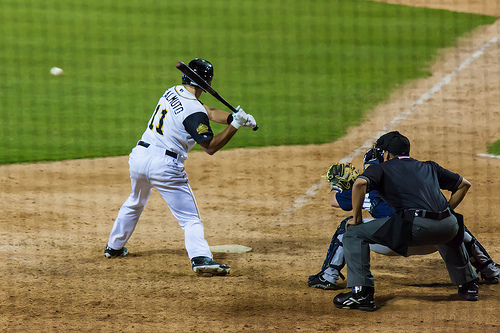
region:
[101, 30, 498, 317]
Men playing baseball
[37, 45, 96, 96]
baseball in the air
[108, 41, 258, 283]
man in hitting stance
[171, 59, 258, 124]
man holding black bat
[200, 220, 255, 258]
hexagon shaped object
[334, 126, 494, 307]
empire watching the pitch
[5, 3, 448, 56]
short green grassy field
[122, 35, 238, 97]
man has black helmet on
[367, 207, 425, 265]
black towel hanging out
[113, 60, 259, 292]
man in white baseball uniform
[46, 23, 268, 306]
a baseball player focused on the ball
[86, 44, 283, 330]
a baseball player at bat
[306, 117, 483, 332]
an umpire and a catcher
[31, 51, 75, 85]
a baseball speeding towards the batter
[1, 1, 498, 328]
a baseball game going on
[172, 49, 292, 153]
a black baseball bat and a batting helmet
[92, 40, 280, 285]
an athlete looking to hit the ball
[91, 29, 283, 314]
an athlete looking to swing his bat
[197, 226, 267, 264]
home plate on a baseball diamond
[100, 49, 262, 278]
A baseball player preparing to swing his bat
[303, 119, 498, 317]
A catcher standing at home plate.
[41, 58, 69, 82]
a baseball flying through the air.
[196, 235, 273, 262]
a base near a baseball player.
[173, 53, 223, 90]
a hard blue hat.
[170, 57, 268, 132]
a bat in a players hand.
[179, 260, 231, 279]
a foot on the right shoe.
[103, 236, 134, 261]
the left shoe on a foot.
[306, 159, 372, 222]
a catchers MIT on a catcher.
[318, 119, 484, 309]
a man dressed in dark blue.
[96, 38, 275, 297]
a baseball player preparing to bat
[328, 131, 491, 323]
umpire getting ready to judge the pitch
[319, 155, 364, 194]
a catcher's mitt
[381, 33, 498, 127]
chalk first base line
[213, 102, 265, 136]
white batting gloves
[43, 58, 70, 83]
a baseball being thrown toward the catcher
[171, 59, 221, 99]
a black batting helmet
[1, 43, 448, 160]
the infield is covered with grass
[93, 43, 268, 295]
the baseball player wears number eleven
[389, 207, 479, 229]
a black belt holding up the pants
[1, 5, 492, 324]
A baseball game is being played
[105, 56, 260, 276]
This man is the batter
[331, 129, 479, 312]
This is the umpire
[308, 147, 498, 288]
the catcher is in front of the umpire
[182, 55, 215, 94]
The batter is wearing a helmet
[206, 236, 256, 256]
This is home plate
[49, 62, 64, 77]
The baseball is in flight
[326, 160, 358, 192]
The catcher's mitt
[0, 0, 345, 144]
The infield is grass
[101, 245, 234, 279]
The batter is wearing cleats